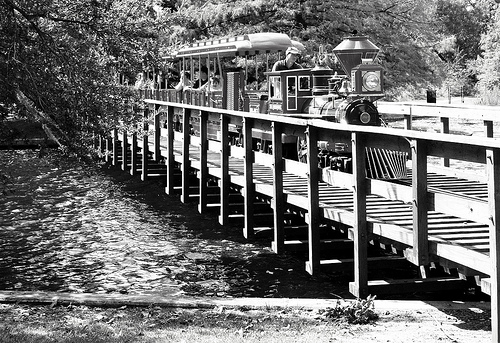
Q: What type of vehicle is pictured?
A: A train.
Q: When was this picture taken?
A: During the day.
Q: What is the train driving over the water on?
A: A bridge.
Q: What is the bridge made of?
A: Wood.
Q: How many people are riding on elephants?
A: Zero.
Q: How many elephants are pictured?
A: Zero.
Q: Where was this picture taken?
A: In an amusement park.